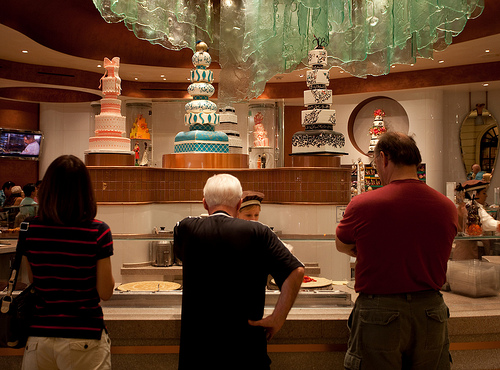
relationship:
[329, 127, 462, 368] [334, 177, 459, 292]
male in shirt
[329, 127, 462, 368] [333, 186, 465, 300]
male wearing a shirt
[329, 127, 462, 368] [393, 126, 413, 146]
male has a bald spot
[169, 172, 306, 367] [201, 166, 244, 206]
man has hair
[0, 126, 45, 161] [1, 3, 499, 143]
television hanging from ceiling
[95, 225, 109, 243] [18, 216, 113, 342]
stripe on shirt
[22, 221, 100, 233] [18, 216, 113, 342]
stripe on shirt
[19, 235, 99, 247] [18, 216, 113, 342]
stripe on shirt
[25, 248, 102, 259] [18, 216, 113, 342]
stripe on shirt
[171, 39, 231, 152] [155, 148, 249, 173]
cake on top shelf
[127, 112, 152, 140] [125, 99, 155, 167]
doll on case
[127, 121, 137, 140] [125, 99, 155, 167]
doll on case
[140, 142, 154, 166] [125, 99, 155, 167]
doll on case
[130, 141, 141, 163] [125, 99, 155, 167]
doll on case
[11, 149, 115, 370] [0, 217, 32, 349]
woman carrying a purse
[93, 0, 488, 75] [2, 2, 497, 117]
decor hanging from ceiling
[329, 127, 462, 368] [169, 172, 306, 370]
male standing next to man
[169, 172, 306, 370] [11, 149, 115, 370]
man standing next to woman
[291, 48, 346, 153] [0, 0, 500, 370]
cake arranged around bakery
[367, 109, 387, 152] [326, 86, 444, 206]
cake sits in wall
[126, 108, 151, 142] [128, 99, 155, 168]
cake in a case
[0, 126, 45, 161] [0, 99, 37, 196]
television on wall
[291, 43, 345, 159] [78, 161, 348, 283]
cake on display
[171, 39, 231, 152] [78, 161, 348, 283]
cake on display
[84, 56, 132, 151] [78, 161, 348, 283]
cake on display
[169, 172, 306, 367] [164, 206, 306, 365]
man in t-shirt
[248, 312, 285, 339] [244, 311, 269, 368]
hand on hip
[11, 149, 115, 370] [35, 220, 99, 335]
woman in shirt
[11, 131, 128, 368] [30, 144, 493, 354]
woman working in bakery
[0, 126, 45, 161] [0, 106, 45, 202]
television hanging from wall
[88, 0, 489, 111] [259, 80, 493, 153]
decor on wall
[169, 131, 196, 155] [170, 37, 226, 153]
blue trim on cake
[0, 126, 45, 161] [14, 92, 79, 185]
television on wall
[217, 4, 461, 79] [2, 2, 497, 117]
glass hanging from ceiling